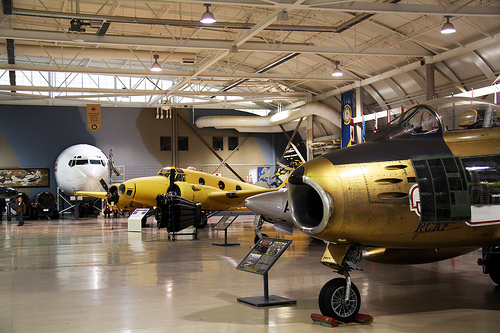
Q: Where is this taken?
A: A airplane museum.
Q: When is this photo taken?
A: Daytime.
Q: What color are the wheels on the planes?
A: Black.